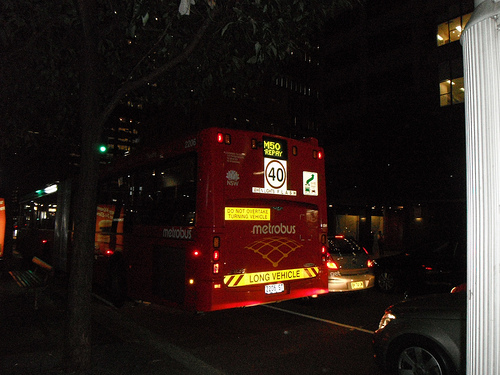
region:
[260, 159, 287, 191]
number 40 on back of the bus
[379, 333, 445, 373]
tire on the car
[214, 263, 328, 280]
yellow sign on the back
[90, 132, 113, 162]
green light in the sky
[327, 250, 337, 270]
headlight on the car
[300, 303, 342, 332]
white line on the road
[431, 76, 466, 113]
window on the building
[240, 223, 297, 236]
metrobus logo on the bus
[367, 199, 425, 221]
lights on the building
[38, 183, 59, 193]
white light on the bus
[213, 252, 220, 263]
rear brake light on the bus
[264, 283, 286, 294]
white license plate on the bus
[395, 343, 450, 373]
front tire on a vehicle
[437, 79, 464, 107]
light on in the building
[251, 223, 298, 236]
public bus logo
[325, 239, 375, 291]
rear end of car on the road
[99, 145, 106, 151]
green street light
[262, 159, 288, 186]
number forty on the bus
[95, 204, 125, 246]
food advertisement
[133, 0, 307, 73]
green leaves on a tree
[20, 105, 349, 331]
a bus on the road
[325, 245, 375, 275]
tail lights of a car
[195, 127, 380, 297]
a car close to a bus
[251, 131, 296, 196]
a sign with number 40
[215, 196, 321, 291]
yellow stickers behind a bus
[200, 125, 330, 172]
two tail lights on top of bus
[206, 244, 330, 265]
two tail lights on back of bus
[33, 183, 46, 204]
a green light on front a bus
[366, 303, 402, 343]
a front light of car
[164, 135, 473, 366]
a car behind a bus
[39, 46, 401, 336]
a fire truck at night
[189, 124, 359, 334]
break lights on a fire truck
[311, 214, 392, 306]
a car beside the firetruck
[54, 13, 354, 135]
a building in the background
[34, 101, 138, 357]
a tree near the street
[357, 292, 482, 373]
a front end of a car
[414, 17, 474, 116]
lights in the building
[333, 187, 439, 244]
lights at an entrance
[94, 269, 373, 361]
a dark street for driving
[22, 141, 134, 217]
green lights on the street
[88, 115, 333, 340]
the bus is red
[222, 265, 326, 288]
The signs are yellow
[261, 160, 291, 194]
The number has a circle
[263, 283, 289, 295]
the license plate is white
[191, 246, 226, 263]
the lights are red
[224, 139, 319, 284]
the bus has lettering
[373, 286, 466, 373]
there is a car behind the bus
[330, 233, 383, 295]
there is a car beside the bus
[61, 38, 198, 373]
the tree is tall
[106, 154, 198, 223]
the bus has windows